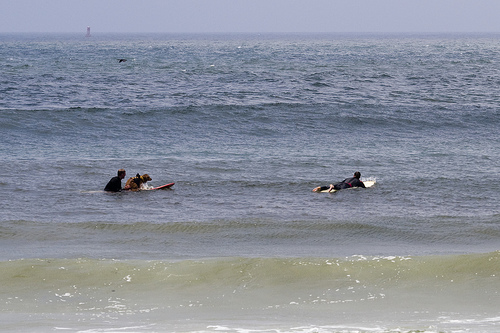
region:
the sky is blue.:
[8, 5, 458, 55]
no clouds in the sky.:
[10, 3, 474, 66]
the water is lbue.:
[19, 28, 441, 112]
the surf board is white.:
[306, 150, 380, 208]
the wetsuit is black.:
[311, 154, 368, 201]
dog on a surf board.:
[104, 155, 190, 209]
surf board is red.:
[129, 164, 175, 204]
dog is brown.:
[111, 159, 152, 199]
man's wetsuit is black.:
[87, 148, 130, 207]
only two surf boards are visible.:
[65, 131, 405, 236]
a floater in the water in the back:
[69, 18, 103, 39]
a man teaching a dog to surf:
[85, 151, 202, 201]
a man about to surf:
[309, 167, 408, 202]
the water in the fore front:
[79, 219, 352, 321]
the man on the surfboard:
[296, 165, 380, 200]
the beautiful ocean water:
[128, 40, 428, 120]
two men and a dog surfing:
[2, 153, 397, 208]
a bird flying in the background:
[103, 56, 155, 71]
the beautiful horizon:
[96, 1, 440, 20]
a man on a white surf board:
[323, 173, 401, 210]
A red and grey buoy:
[76, 20, 118, 57]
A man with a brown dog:
[91, 161, 207, 215]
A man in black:
[89, 155, 127, 207]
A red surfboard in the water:
[133, 161, 182, 207]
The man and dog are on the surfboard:
[90, 149, 176, 201]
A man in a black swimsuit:
[296, 152, 418, 197]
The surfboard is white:
[313, 147, 378, 217]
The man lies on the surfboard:
[306, 134, 410, 215]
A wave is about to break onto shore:
[73, 235, 486, 315]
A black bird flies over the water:
[107, 50, 134, 67]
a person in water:
[96, 162, 123, 197]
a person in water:
[126, 160, 159, 200]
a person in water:
[308, 137, 383, 199]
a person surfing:
[100, 155, 132, 209]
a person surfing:
[132, 168, 192, 211]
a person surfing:
[301, 148, 383, 203]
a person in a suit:
[311, 161, 383, 206]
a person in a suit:
[96, 157, 131, 204]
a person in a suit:
[131, 166, 154, 199]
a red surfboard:
[151, 167, 176, 196]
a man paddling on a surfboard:
[321, 159, 448, 204]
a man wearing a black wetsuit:
[296, 154, 441, 236]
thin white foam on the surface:
[354, 248, 424, 277]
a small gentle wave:
[100, 257, 280, 283]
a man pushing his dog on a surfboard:
[89, 134, 199, 207]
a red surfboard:
[156, 177, 180, 194]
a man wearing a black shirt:
[106, 158, 128, 209]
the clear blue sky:
[190, 3, 345, 35]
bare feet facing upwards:
[311, 184, 349, 196]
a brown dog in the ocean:
[131, 172, 158, 187]